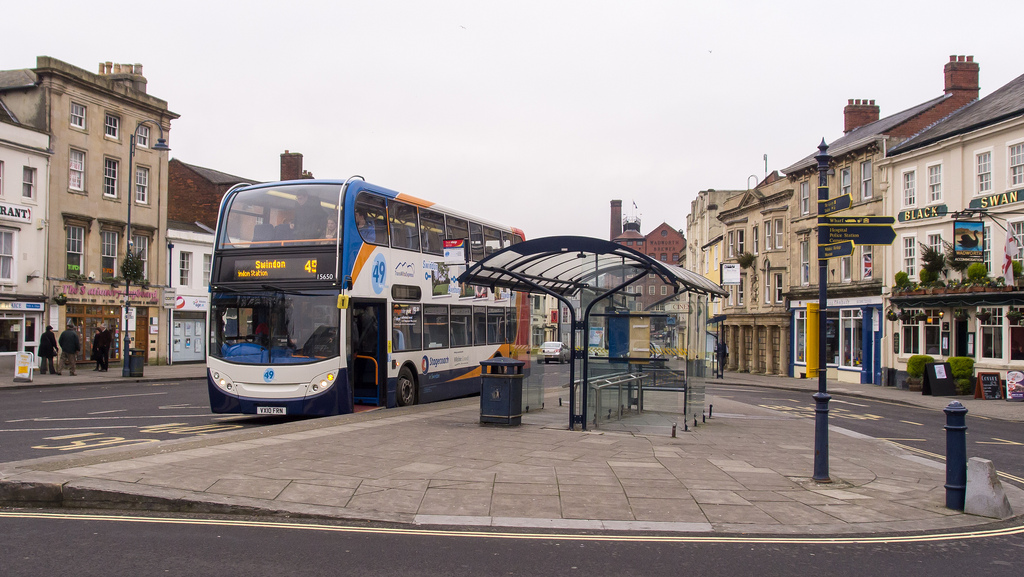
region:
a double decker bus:
[204, 176, 531, 421]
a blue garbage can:
[471, 348, 528, 429]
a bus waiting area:
[460, 233, 739, 434]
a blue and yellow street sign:
[808, 133, 900, 488]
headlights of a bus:
[208, 367, 339, 397]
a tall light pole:
[120, 117, 175, 383]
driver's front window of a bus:
[209, 291, 339, 369]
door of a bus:
[343, 288, 389, 406]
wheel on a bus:
[391, 361, 426, 406]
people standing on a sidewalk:
[38, 320, 118, 381]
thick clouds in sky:
[412, 29, 643, 113]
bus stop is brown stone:
[298, 398, 616, 544]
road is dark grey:
[23, 342, 210, 479]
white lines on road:
[61, 348, 145, 438]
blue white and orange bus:
[210, 184, 590, 450]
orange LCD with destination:
[207, 249, 300, 301]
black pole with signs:
[778, 176, 927, 489]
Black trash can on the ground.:
[473, 350, 525, 426]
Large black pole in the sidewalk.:
[807, 186, 850, 490]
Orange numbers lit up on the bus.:
[304, 253, 333, 276]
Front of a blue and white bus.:
[193, 154, 391, 437]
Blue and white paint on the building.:
[778, 282, 883, 352]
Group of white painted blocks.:
[406, 511, 719, 549]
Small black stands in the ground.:
[637, 420, 686, 437]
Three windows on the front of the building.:
[38, 89, 175, 153]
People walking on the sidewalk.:
[43, 288, 104, 358]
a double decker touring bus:
[209, 176, 526, 423]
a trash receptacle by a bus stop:
[480, 341, 529, 419]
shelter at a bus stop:
[465, 211, 716, 442]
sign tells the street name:
[815, 142, 885, 481]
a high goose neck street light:
[120, 107, 171, 380]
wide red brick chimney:
[837, 94, 885, 134]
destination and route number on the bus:
[219, 242, 334, 284]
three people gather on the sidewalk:
[37, 315, 114, 372]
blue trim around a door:
[859, 300, 889, 390]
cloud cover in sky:
[3, 0, 1022, 242]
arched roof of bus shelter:
[470, 233, 720, 445]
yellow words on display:
[228, 252, 324, 281]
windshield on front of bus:
[209, 293, 343, 366]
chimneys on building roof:
[794, 49, 978, 170]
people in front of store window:
[38, 299, 125, 373]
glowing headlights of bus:
[209, 372, 337, 389]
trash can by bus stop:
[467, 342, 535, 437]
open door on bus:
[350, 285, 402, 409]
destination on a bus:
[223, 247, 296, 282]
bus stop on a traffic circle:
[457, 225, 727, 447]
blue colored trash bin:
[477, 353, 531, 433]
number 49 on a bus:
[300, 256, 321, 282]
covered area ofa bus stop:
[455, 234, 730, 324]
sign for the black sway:
[893, 190, 1021, 226]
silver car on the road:
[536, 334, 576, 369]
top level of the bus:
[202, 177, 538, 288]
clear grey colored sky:
[0, 0, 1021, 256]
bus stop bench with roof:
[444, 227, 738, 437]